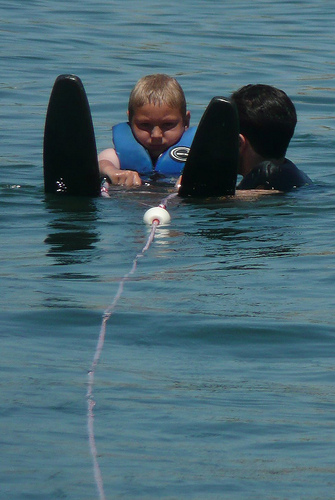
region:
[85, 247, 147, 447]
Rope is under water.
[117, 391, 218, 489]
Water is blue in color.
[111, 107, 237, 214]
Boy wearing blue life vest.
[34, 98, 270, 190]
Boy wearing black skis on feet.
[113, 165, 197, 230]
Boy holding on to handle connected to rope.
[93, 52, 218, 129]
Boy has blonde hair.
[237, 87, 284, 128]
Person has dark hair.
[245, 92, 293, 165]
Person has short hair.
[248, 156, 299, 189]
Person wearing black top.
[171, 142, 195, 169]
White logo on blue vest.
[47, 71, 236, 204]
little boy learning to water ski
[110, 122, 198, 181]
blue life jacket on the boy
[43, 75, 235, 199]
black water skis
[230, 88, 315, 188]
water ski instructor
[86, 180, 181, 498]
rope from boy to the boat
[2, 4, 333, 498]
blue water in the lake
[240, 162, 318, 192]
black life vest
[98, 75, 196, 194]
young man with blonde hair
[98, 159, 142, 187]
young man's right hand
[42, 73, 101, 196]
young man's right water ski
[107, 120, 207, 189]
boy wears blue floatation device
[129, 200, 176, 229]
white buoy is on water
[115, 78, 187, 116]
boy has brown hair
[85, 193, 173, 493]
line from floatation buoy is clear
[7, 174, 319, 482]
water is deep blue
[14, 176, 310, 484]
water is very calm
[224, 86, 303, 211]
person has dark hair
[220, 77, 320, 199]
person looking at boy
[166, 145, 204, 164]
black and white logo on floatation device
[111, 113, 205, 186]
life vest is blue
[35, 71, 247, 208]
A pair of water skiies.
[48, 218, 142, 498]
A rope in the water.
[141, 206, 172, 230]
A white ball on the rope.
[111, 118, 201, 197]
A blue life jacket.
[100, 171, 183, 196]
Handle of the rope.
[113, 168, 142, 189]
The boy hangs on.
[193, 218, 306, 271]
Ripples in the water.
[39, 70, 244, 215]
A boy preparing to water skii.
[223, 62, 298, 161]
The back of a boys head.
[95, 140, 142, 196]
The arm of a boy.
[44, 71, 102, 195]
a wide black water ski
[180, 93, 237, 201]
a wide black water ski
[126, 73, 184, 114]
the blond hair of a boy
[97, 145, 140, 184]
the arm of a boy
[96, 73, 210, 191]
a blond boy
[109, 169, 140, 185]
the hand of a boy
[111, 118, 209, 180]
a bright blue life jacket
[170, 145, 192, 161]
a black and grey logo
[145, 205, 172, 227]
a white buoy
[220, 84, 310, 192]
a man in the water